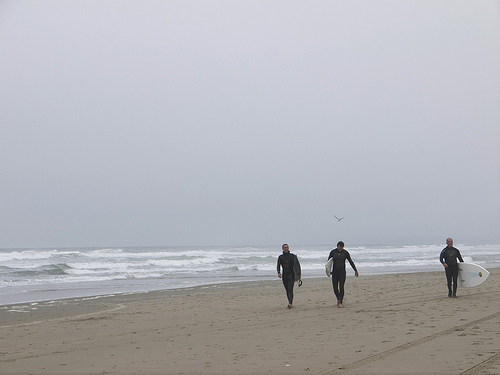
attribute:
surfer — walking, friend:
[276, 243, 303, 309]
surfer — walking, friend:
[326, 240, 358, 304]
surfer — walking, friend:
[441, 237, 465, 296]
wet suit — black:
[275, 253, 297, 303]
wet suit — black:
[330, 247, 354, 301]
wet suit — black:
[441, 251, 465, 293]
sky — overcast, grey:
[2, 0, 500, 250]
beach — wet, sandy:
[1, 269, 500, 372]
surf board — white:
[453, 260, 491, 295]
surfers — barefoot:
[275, 243, 302, 309]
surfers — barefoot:
[324, 240, 360, 309]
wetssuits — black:
[256, 225, 478, 312]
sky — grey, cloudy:
[104, 43, 489, 253]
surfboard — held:
[292, 265, 311, 282]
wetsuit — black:
[437, 248, 467, 290]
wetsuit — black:
[326, 248, 356, 298]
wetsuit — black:
[278, 253, 303, 302]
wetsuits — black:
[276, 252, 300, 303]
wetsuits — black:
[324, 248, 358, 300]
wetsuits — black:
[435, 246, 468, 291]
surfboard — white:
[438, 261, 480, 285]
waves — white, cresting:
[3, 242, 498, 284]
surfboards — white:
[315, 247, 335, 285]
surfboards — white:
[450, 252, 493, 293]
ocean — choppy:
[28, 248, 243, 279]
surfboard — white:
[457, 257, 493, 302]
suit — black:
[274, 222, 309, 304]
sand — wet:
[8, 273, 496, 367]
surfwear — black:
[256, 234, 487, 314]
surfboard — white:
[324, 254, 334, 278]